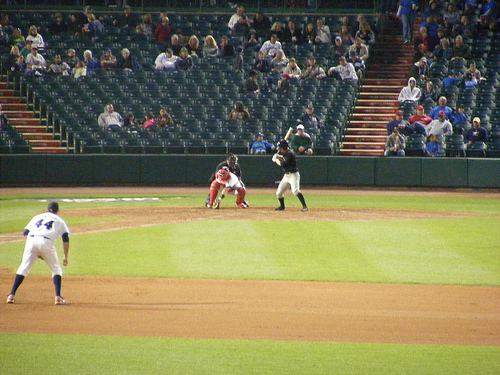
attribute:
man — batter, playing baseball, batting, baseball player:
[272, 138, 310, 213]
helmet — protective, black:
[276, 138, 289, 149]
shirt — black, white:
[280, 149, 297, 170]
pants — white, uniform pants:
[277, 170, 301, 197]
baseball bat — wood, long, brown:
[275, 127, 293, 153]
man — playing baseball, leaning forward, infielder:
[6, 200, 72, 302]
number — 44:
[33, 217, 55, 229]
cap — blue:
[48, 200, 59, 211]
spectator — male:
[432, 96, 452, 119]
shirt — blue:
[431, 105, 451, 120]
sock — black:
[279, 197, 286, 208]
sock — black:
[298, 192, 308, 208]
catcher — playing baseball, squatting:
[209, 167, 249, 209]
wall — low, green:
[0, 155, 500, 187]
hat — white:
[297, 124, 305, 130]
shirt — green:
[291, 133, 312, 151]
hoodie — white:
[397, 75, 421, 101]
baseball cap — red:
[218, 166, 229, 174]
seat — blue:
[98, 137, 120, 146]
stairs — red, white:
[0, 75, 83, 154]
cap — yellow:
[473, 116, 482, 123]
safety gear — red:
[210, 170, 247, 203]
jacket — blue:
[447, 111, 468, 124]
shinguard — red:
[237, 186, 246, 204]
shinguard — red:
[210, 182, 220, 204]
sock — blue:
[53, 275, 64, 295]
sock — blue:
[11, 273, 24, 294]